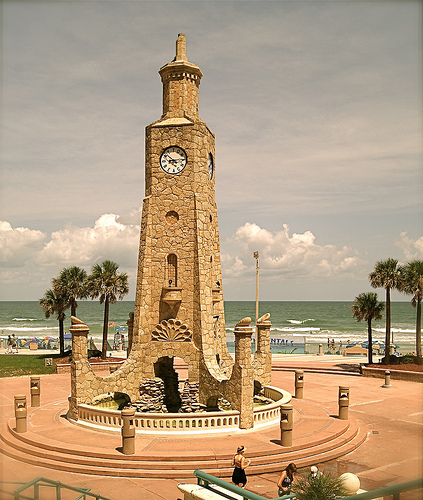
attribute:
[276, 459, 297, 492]
woman — standing 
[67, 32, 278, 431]
tower — tall, clock tower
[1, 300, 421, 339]
sea — sea foam, white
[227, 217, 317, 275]
cloud — large, white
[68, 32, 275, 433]
clock tower — stone clock tower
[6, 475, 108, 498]
guard railing — green, metal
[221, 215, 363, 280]
cloud — white, large, in sky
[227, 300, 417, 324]
water — clear, blue, calm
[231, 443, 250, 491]
woman — walking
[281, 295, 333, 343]
waves — small